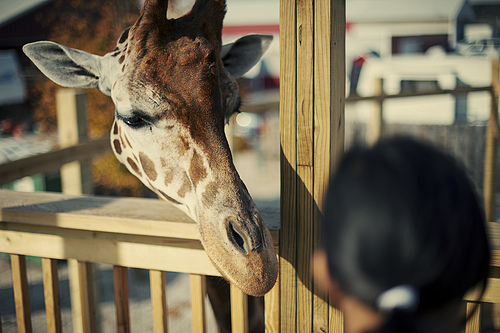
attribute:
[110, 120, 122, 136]
spot — brown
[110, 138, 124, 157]
spot — brown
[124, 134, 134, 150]
spot — brown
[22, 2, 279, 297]
giraffe — sticking head over wood railing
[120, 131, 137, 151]
spot — brown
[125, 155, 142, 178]
spot — brown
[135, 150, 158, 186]
spot — brown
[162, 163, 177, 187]
spot — brown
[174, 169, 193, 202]
spot — brown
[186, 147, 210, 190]
spot — brown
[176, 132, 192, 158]
spot — brown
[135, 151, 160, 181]
brown spot — on giraffe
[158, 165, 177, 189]
brown spot — on giraffe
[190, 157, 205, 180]
brown spot — on giraffe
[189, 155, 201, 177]
brown spot — on giraffe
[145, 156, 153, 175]
brown spot — on giraffe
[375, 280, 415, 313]
ponytail holder — white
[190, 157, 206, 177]
brown spots — on giraffe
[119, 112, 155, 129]
giraffe eye — dark